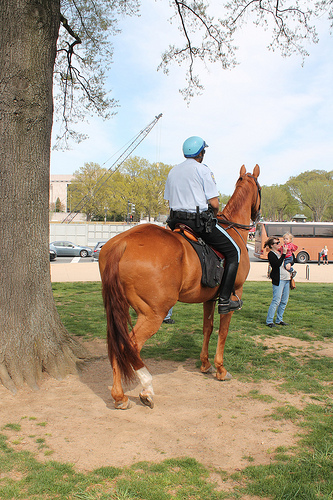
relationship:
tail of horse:
[96, 239, 147, 389] [94, 160, 270, 339]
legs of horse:
[192, 310, 232, 383] [98, 162, 275, 373]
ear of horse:
[239, 164, 245, 176] [95, 159, 262, 407]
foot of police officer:
[217, 297, 242, 314] [163, 135, 244, 317]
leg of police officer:
[206, 227, 243, 312] [163, 135, 244, 317]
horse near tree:
[95, 159, 262, 407] [0, 0, 332, 397]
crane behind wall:
[57, 113, 163, 221] [49, 220, 129, 249]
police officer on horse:
[163, 138, 241, 311] [95, 159, 262, 407]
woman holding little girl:
[264, 237, 292, 327] [277, 231, 298, 277]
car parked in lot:
[50, 240, 92, 258] [51, 221, 330, 261]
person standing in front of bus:
[319, 245, 328, 262] [254, 222, 332, 261]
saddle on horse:
[169, 224, 222, 286] [91, 197, 319, 288]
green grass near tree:
[0, 281, 331, 498] [1, 0, 91, 383]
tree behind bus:
[288, 172, 332, 219] [256, 221, 332, 266]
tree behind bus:
[259, 167, 332, 222] [256, 221, 332, 266]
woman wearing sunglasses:
[262, 237, 291, 328] [270, 241, 278, 245]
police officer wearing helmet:
[163, 135, 244, 317] [180, 135, 206, 163]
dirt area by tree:
[199, 392, 257, 438] [0, 20, 83, 188]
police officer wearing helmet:
[163, 135, 244, 317] [173, 132, 212, 163]